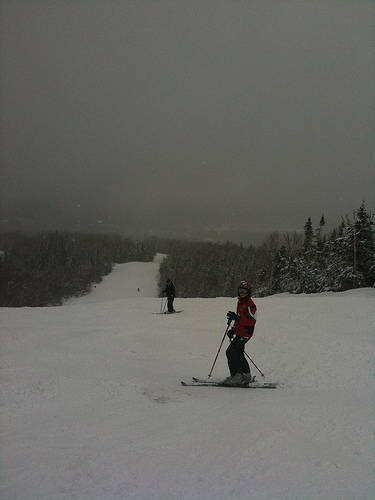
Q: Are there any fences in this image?
A: No, there are no fences.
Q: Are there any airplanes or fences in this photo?
A: No, there are no fences or airplanes.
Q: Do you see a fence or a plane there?
A: No, there are no fences or airplanes.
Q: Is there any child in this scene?
A: Yes, there is a child.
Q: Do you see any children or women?
A: Yes, there is a child.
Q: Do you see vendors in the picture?
A: No, there are no vendors.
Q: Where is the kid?
A: The kid is in the snow.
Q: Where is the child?
A: The kid is in the snow.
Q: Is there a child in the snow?
A: Yes, there is a child in the snow.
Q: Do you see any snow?
A: Yes, there is snow.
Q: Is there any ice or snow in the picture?
A: Yes, there is snow.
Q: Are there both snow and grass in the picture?
A: No, there is snow but no grass.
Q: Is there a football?
A: No, there are no footballs.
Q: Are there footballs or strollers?
A: No, there are no footballs or strollers.